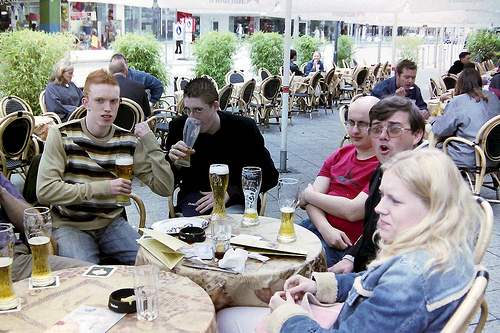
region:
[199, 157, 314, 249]
Beer is on a small table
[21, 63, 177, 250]
Person is wearing a long shirt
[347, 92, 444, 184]
Person is wearing sunglasses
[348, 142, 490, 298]
Woman has blonde hair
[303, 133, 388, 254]
Person is wearing a red shirt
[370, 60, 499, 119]
People are in the background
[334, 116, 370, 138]
Person is wearing eyeglasses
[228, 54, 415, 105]
Empty chairs are in the background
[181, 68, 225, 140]
Person has dark colored hair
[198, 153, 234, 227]
Beer cup is full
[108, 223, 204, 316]
Ash trays on the tables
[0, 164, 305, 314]
Beer glasses on the tables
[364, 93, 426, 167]
Man with the shocked fave and glasses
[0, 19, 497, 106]
Bushes that line the street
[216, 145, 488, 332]
Blonde woman nearest the camera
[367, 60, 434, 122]
Man with a spoon full of food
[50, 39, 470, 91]
Street that the patio seating is next to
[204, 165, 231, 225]
Beer glass on the table with the most beer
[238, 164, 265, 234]
glass on the table with the least amount of beer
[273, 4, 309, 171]
The pole holding the umbrella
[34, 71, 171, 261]
young man drinking beer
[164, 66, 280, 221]
young man drinking beer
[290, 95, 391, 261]
a person in a red shirt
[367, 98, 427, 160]
young man with his mouth open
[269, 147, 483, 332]
a young lady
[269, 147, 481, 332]
a blond haired woman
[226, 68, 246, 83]
an empty chair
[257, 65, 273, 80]
an empty chair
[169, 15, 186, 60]
a person walking in the distance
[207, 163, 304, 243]
three beers on the table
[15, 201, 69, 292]
golden colored beer in a glass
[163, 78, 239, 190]
man drinking beer out of glass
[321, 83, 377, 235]
man wearing a red shirt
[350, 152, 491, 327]
woman sitting in chair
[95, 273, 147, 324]
black ashtray on table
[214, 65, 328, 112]
tables and chairs at outside cafe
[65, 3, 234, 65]
glass storefront windows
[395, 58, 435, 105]
man eating at a distance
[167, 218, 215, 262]
black ashtray sitting on table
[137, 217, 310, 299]
table top covered with papers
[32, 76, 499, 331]
people sitting around table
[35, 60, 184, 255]
man holding beer in hand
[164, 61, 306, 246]
man drinking beer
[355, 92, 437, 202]
man wearing glasses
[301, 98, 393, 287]
man wearing red shirt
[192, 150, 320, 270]
glasses of beer on table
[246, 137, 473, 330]
lady wearing denim jacket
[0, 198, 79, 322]
two glasses of beer on table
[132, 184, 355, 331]
round tables with drinks and menus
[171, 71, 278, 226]
man wearing black jacket